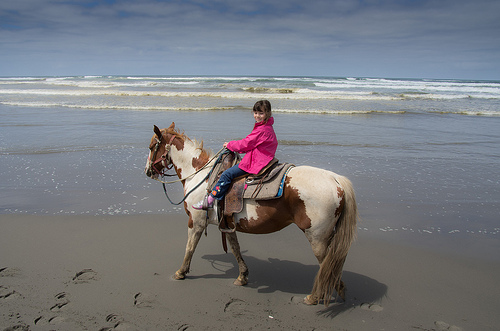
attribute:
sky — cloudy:
[3, 1, 498, 78]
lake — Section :
[326, 98, 386, 130]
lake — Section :
[302, 69, 494, 152]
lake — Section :
[12, 74, 497, 211]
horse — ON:
[145, 122, 355, 303]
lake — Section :
[153, 77, 350, 139]